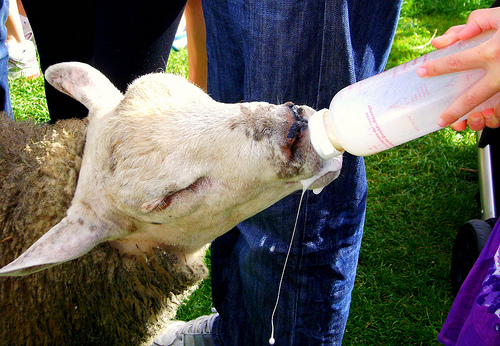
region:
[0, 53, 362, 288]
the head of a sheep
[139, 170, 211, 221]
the eye of a sheep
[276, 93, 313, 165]
the nose of a sheep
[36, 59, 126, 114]
the ear of a sheep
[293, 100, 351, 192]
the mouth of a sheep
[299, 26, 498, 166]
a plastic milk bottle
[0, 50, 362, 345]
a sheep drinking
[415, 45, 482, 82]
the finger of a person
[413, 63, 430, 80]
the finger nail of a person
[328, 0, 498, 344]
green grass on the ground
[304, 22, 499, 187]
white plastic feeding bottle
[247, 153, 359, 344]
milk dripping from sheep's mouth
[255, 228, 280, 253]
milk spots on jeans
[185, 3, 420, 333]
dark blue denim jeans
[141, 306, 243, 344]
white athletic foot wear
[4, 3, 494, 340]
dark green low cut grass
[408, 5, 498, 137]
hands holding plastic bottle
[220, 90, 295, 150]
brown spot on sheep's nose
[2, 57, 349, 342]
sheep drinking with head back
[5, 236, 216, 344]
dirty blackened sheep fur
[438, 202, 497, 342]
Purple clothing in the bottom right side of the photo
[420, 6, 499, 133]
Hands holding a bottle of milk for the sheep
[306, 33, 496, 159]
The milk bottle for feeding the sheep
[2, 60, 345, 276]
The smooth white face of the sheep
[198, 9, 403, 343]
Someone's blue jean clad legs in the middle of the photo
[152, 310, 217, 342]
The white sneaker of the guy in blue jeans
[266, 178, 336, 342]
Milk dripping out of the sheep's mouth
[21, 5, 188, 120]
Someone's black clad legs on the left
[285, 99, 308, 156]
The black and pink nose of the sheep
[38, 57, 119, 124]
The left white and gray ear of the sheep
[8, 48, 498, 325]
Sheep is drinking milk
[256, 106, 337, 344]
Milk drips down from sheep's chin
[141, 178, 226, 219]
The lamb's eyes are closed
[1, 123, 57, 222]
The sheep's coat is brown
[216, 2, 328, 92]
The jeans are blue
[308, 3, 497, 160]
A person holding a milk bottle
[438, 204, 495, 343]
A purple swatch of fabric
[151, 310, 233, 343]
Tennis shoe is white and blue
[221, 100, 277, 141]
A brown design on sheep's nose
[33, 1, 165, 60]
The pants are black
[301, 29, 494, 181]
plastic bottle of milk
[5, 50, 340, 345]
sheep drinking milk from bottle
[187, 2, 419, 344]
dark blue denim pants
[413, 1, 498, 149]
hands gripping plastic bottle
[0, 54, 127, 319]
laid back sheep's ears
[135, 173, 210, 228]
closed right eye of sheep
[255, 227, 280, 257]
drops of milk on denim pants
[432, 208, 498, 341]
purple cloth in bottom right corner